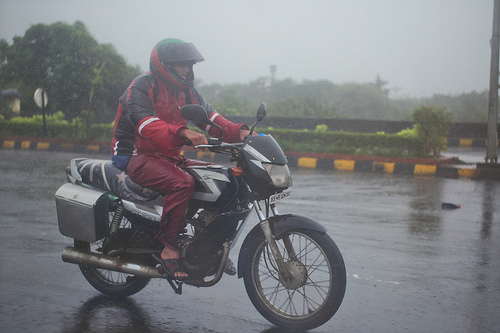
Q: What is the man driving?
A: A motorcycle.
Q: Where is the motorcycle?
A: Street.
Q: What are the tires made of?
A: Rubber.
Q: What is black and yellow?
A: Curb.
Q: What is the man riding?
A: Motorcycle.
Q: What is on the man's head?
A: Helmet.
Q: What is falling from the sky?
A: Rain.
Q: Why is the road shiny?
A: Wet.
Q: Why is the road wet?
A: Rain.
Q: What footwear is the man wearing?
A: Sandals.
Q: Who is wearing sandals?
A: A man.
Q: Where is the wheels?
A: On motorcycle.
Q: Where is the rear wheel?
A: Back of bike.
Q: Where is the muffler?
A: On motorcycle.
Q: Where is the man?
A: On bike.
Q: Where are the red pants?
A: On man.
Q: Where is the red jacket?
A: On man.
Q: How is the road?
A: Wet.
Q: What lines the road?
A: Hedges.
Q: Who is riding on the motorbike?
A: A man.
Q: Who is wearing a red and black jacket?
A: The man.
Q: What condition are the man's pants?
A: Wet.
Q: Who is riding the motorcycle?
A: A man.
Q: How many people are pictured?
A: One.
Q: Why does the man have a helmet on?
A: To protect his head.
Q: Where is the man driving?
A: In the street.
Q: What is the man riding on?
A: A motorcycle.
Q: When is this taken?
A: Daytime.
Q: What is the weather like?
A: Rainy and foggy.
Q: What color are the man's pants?
A: Red.